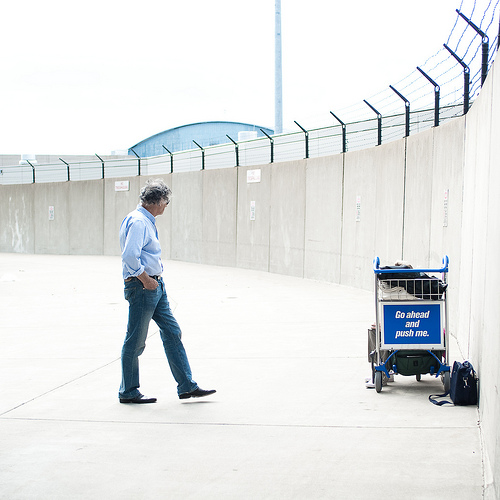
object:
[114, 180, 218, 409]
man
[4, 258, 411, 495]
ground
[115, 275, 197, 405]
jeans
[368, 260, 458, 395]
cart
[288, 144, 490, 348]
against wall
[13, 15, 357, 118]
sky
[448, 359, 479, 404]
bag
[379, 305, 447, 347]
sign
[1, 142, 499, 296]
wall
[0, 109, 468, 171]
wire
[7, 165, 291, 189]
wall top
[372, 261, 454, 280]
handle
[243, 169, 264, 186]
sign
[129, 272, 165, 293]
hands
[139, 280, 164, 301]
pocket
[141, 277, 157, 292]
hand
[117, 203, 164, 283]
shirt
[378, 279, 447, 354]
cart back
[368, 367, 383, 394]
wheel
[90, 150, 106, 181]
rods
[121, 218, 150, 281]
sleeve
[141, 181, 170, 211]
hair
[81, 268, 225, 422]
walking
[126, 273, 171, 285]
belt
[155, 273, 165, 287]
buckle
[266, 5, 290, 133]
smoke stack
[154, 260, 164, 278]
button